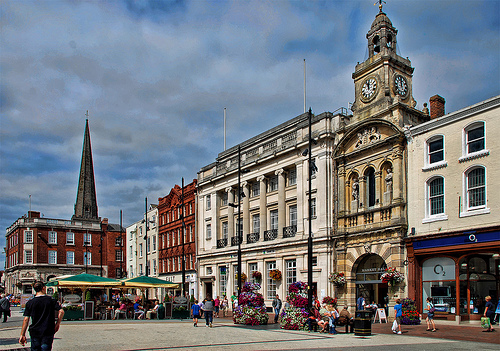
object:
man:
[16, 280, 64, 351]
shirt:
[23, 294, 63, 335]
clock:
[359, 76, 377, 99]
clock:
[392, 75, 409, 96]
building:
[403, 100, 499, 327]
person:
[394, 298, 402, 335]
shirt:
[394, 304, 403, 314]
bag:
[390, 319, 398, 333]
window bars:
[428, 193, 443, 198]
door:
[349, 251, 387, 318]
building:
[125, 203, 160, 300]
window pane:
[421, 211, 445, 223]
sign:
[376, 307, 387, 318]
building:
[4, 109, 105, 306]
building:
[329, 0, 429, 321]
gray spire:
[70, 109, 101, 222]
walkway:
[0, 304, 499, 350]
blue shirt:
[191, 304, 200, 315]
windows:
[291, 213, 296, 219]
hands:
[367, 79, 370, 88]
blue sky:
[0, 0, 499, 271]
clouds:
[0, 0, 499, 271]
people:
[190, 298, 202, 326]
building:
[158, 178, 197, 301]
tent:
[45, 271, 122, 286]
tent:
[122, 274, 182, 286]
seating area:
[55, 285, 182, 319]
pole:
[237, 144, 242, 308]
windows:
[47, 250, 58, 264]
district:
[0, 0, 499, 349]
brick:
[390, 246, 400, 254]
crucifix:
[85, 110, 90, 119]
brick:
[39, 245, 46, 248]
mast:
[224, 107, 227, 151]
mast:
[302, 57, 306, 112]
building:
[197, 58, 353, 315]